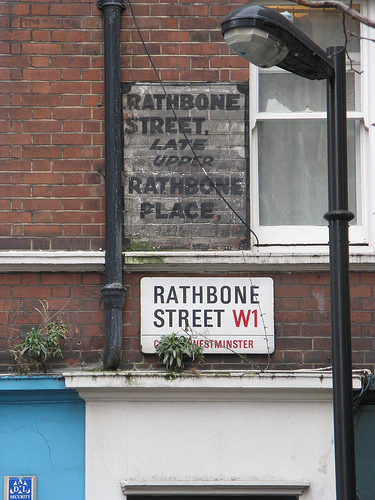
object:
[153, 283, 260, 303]
black words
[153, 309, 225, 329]
black words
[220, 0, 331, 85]
light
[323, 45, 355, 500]
pole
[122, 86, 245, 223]
text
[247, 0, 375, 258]
window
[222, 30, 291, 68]
glass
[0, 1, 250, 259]
bricks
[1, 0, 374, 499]
building